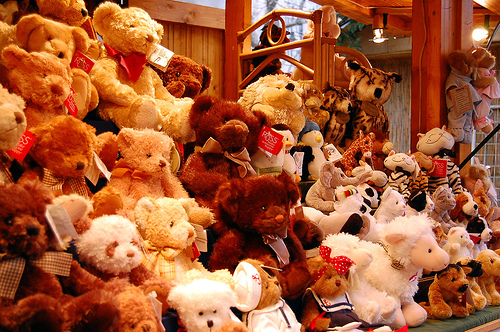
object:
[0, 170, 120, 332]
bear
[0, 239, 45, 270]
neck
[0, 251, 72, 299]
bow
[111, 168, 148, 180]
brown bow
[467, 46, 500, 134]
bear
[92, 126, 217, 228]
bear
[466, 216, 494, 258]
toy dog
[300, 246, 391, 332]
bear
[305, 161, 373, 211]
elephant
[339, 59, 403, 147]
bear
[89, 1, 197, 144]
bear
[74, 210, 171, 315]
bear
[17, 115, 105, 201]
bear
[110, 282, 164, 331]
bear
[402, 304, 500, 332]
table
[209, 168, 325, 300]
bear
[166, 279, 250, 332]
animal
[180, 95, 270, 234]
animal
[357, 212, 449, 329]
animal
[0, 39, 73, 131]
animal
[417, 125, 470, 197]
animal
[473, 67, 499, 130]
outfit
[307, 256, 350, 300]
head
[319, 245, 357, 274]
bow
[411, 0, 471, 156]
wall